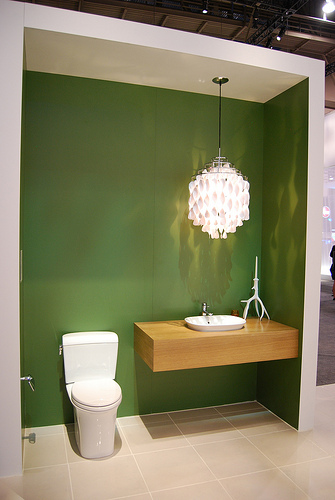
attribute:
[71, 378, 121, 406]
lid — closed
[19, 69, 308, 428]
walls — green moss, green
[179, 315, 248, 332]
sink — white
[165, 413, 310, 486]
tiles — large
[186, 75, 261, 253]
lamp — on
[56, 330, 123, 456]
toilet — white, modern, sleek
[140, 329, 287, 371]
counter — wooden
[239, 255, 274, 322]
decoration — white